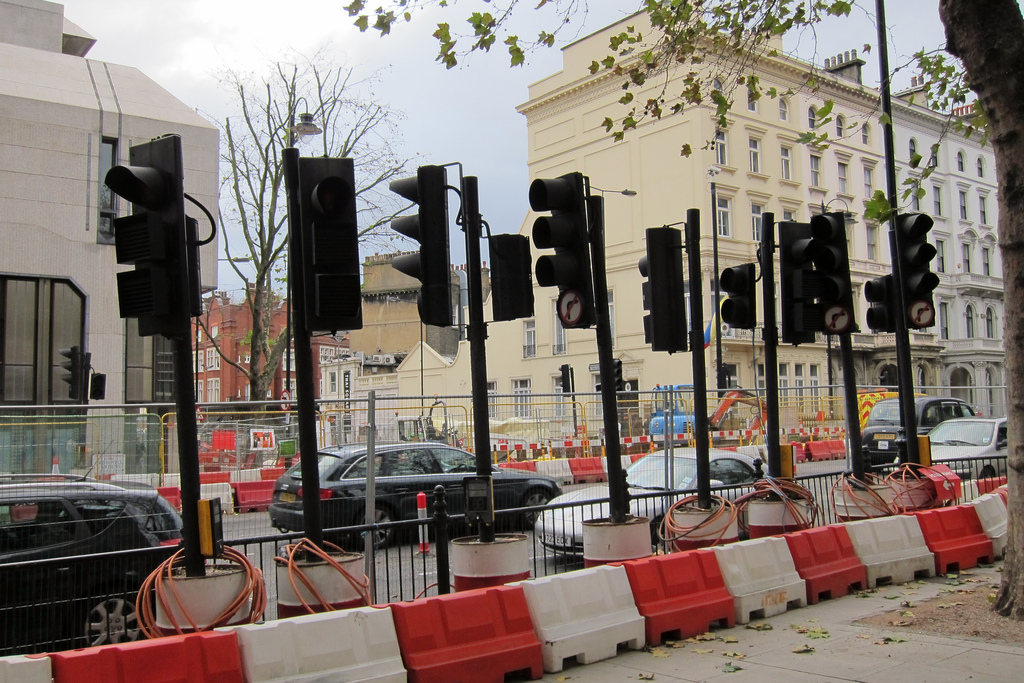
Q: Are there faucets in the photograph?
A: No, there are no faucets.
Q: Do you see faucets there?
A: No, there are no faucets.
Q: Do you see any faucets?
A: No, there are no faucets.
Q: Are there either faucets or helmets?
A: No, there are no faucets or helmets.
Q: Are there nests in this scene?
A: No, there are no nests.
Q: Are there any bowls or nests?
A: No, there are no nests or bowls.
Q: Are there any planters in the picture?
A: No, there are no planters.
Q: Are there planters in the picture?
A: No, there are no planters.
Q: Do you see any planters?
A: No, there are no planters.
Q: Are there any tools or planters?
A: No, there are no planters or tools.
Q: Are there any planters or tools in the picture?
A: No, there are no planters or tools.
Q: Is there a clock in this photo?
A: No, there are no clocks.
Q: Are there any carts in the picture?
A: No, there are no carts.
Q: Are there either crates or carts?
A: No, there are no carts or crates.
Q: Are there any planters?
A: No, there are no planters.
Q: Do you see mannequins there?
A: No, there are no mannequins.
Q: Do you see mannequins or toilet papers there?
A: No, there are no mannequins or toilet papers.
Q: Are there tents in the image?
A: No, there are no tents.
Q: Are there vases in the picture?
A: No, there are no vases.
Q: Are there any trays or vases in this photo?
A: No, there are no vases or trays.